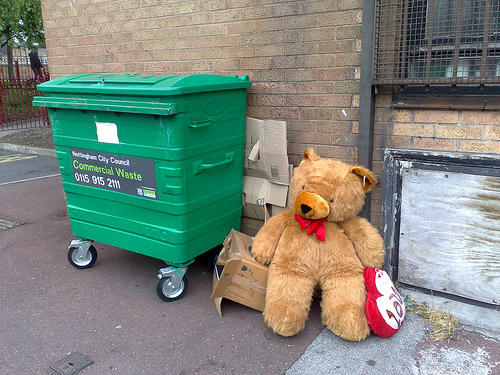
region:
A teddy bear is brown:
[250, 145, 388, 341]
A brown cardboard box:
[206, 225, 267, 320]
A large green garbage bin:
[27, 65, 247, 302]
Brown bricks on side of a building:
[35, 0, 495, 235]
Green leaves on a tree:
[0, 0, 42, 50]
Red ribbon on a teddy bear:
[290, 207, 330, 243]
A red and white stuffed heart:
[360, 260, 410, 340]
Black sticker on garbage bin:
[65, 140, 161, 201]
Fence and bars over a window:
[370, 1, 495, 91]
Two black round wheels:
[62, 232, 188, 302]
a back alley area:
[5, 8, 496, 351]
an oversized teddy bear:
[251, 139, 415, 373]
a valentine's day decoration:
[353, 263, 418, 338]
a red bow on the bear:
[291, 206, 333, 242]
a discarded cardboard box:
[206, 231, 263, 311]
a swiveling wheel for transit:
[140, 258, 200, 325]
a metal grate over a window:
[375, 5, 497, 78]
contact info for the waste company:
[60, 145, 177, 205]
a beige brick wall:
[148, 17, 316, 64]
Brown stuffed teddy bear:
[253, 148, 383, 340]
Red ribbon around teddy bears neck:
[294, 215, 332, 243]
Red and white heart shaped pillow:
[363, 265, 409, 337]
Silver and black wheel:
[151, 266, 189, 302]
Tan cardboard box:
[201, 228, 264, 318]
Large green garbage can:
[29, 70, 254, 250]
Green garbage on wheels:
[30, 65, 247, 302]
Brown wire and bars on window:
[375, 5, 495, 94]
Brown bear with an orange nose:
[289, 191, 331, 221]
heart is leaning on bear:
[356, 269, 386, 306]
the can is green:
[174, 108, 211, 144]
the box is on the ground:
[233, 294, 263, 319]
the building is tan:
[101, 16, 129, 42]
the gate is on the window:
[402, 7, 453, 44]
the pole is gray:
[352, 35, 379, 72]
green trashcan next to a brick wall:
[26, 52, 243, 324]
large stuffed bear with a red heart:
[250, 144, 413, 351]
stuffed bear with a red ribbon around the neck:
[281, 151, 380, 238]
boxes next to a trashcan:
[59, 63, 284, 317]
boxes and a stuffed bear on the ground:
[246, 131, 353, 338]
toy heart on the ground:
[362, 264, 419, 351]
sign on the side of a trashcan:
[67, 127, 173, 228]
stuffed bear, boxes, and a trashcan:
[33, 61, 363, 334]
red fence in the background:
[3, 57, 31, 199]